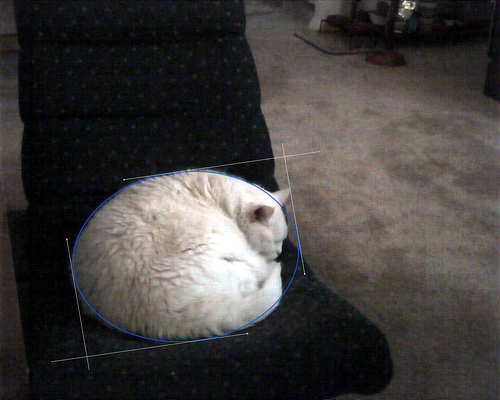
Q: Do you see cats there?
A: Yes, there is a cat.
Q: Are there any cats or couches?
A: Yes, there is a cat.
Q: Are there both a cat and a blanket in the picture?
A: No, there is a cat but no blankets.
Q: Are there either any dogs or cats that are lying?
A: Yes, the cat is lying.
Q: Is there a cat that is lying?
A: Yes, there is a cat that is lying.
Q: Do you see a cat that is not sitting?
A: Yes, there is a cat that is lying .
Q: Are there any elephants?
A: No, there are no elephants.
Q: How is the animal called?
A: The animal is a cat.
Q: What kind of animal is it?
A: The animal is a cat.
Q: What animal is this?
A: This is a cat.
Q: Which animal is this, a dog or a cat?
A: This is a cat.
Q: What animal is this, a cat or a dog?
A: This is a cat.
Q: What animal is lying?
A: The animal is a cat.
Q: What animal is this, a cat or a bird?
A: This is a cat.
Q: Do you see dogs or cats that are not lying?
A: No, there is a cat but it is lying.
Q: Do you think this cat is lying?
A: Yes, the cat is lying.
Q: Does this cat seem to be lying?
A: Yes, the cat is lying.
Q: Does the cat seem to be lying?
A: Yes, the cat is lying.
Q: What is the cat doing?
A: The cat is lying.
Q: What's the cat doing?
A: The cat is lying.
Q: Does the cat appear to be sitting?
A: No, the cat is lying.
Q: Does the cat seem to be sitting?
A: No, the cat is lying.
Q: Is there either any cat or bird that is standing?
A: No, there is a cat but it is lying.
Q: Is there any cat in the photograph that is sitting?
A: No, there is a cat but it is lying.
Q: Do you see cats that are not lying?
A: No, there is a cat but it is lying.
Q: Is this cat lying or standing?
A: The cat is lying.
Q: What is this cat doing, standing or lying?
A: The cat is lying.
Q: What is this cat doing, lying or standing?
A: The cat is lying.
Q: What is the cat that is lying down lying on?
A: The cat is lying on the chair.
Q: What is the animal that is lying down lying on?
A: The cat is lying on the chair.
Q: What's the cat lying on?
A: The cat is lying on the chair.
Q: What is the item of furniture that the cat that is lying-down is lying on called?
A: The piece of furniture is a chair.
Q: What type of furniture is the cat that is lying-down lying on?
A: The cat is lying on the chair.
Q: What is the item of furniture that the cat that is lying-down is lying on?
A: The piece of furniture is a chair.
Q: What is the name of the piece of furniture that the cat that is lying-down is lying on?
A: The piece of furniture is a chair.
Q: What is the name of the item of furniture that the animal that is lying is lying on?
A: The piece of furniture is a chair.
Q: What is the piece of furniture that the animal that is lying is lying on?
A: The piece of furniture is a chair.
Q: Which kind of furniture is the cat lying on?
A: The cat is lying on the chair.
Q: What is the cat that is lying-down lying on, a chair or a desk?
A: The cat is lying on a chair.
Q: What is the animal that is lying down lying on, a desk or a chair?
A: The cat is lying on a chair.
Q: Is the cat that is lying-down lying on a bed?
A: No, the cat is lying on the chair.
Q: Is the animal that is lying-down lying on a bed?
A: No, the cat is lying on the chair.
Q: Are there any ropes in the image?
A: No, there are no ropes.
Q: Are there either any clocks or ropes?
A: No, there are no ropes or clocks.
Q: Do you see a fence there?
A: No, there are no fences.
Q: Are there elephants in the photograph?
A: No, there are no elephants.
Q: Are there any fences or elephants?
A: No, there are no elephants or fences.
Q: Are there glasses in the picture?
A: No, there are no glasses.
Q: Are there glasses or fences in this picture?
A: No, there are no glasses or fences.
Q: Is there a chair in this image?
A: Yes, there is a chair.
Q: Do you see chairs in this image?
A: Yes, there is a chair.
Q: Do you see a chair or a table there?
A: Yes, there is a chair.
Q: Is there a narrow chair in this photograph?
A: Yes, there is a narrow chair.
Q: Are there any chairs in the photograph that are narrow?
A: Yes, there is a chair that is narrow.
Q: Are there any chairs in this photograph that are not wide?
A: Yes, there is a narrow chair.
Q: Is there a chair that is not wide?
A: Yes, there is a narrow chair.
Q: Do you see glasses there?
A: No, there are no glasses.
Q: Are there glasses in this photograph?
A: No, there are no glasses.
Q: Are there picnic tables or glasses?
A: No, there are no glasses or picnic tables.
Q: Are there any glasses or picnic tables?
A: No, there are no glasses or picnic tables.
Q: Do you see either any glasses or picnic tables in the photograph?
A: No, there are no glasses or picnic tables.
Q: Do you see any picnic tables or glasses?
A: No, there are no glasses or picnic tables.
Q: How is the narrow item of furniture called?
A: The piece of furniture is a chair.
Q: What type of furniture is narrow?
A: The furniture is a chair.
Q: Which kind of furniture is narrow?
A: The furniture is a chair.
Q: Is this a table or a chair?
A: This is a chair.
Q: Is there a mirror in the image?
A: No, there are no mirrors.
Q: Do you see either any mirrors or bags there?
A: No, there are no mirrors or bags.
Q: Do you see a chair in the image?
A: Yes, there is a chair.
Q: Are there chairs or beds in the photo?
A: Yes, there is a chair.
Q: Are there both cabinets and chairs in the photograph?
A: No, there is a chair but no cabinets.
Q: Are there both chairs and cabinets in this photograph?
A: No, there is a chair but no cabinets.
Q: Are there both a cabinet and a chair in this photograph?
A: No, there is a chair but no cabinets.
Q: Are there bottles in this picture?
A: No, there are no bottles.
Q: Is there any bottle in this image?
A: No, there are no bottles.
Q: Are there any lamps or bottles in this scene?
A: No, there are no bottles or lamps.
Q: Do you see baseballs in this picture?
A: No, there are no baseballs.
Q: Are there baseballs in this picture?
A: No, there are no baseballs.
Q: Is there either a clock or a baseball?
A: No, there are no baseballs or clocks.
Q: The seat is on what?
A: The seat is on the chair.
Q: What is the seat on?
A: The seat is on the chair.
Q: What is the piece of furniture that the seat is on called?
A: The piece of furniture is a chair.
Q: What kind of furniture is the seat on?
A: The seat is on the chair.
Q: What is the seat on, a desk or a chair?
A: The seat is on a chair.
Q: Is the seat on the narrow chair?
A: Yes, the seat is on the chair.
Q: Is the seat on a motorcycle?
A: No, the seat is on the chair.